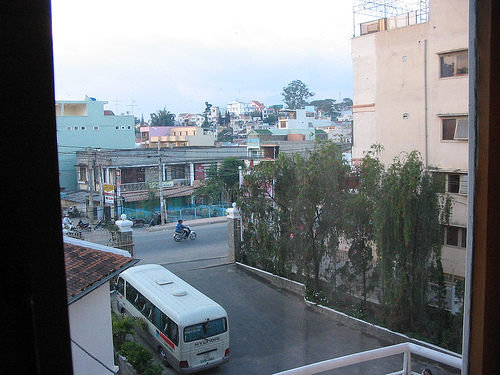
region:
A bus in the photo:
[111, 259, 230, 374]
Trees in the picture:
[295, 187, 398, 294]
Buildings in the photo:
[127, 137, 214, 223]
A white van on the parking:
[134, 264, 221, 372]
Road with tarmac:
[240, 275, 290, 346]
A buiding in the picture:
[410, 46, 443, 128]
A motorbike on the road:
[166, 222, 202, 248]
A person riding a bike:
[168, 218, 196, 239]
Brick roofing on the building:
[80, 246, 103, 276]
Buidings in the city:
[117, 105, 246, 181]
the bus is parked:
[112, 263, 236, 363]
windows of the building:
[418, 33, 482, 316]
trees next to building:
[250, 160, 435, 302]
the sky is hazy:
[153, 30, 270, 86]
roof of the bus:
[149, 265, 204, 317]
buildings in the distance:
[187, 115, 327, 150]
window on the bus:
[161, 306, 225, 348]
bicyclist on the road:
[163, 219, 199, 244]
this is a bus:
[95, 265, 239, 370]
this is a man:
[161, 210, 201, 246]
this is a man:
[165, 211, 190, 231]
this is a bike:
[160, 227, 212, 249]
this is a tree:
[370, 155, 455, 335]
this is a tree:
[280, 150, 351, 295]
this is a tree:
[232, 160, 313, 272]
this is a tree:
[112, 330, 159, 371]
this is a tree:
[178, 158, 248, 214]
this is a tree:
[329, 145, 396, 319]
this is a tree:
[379, 161, 445, 340]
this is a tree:
[279, 130, 355, 320]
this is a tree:
[247, 150, 306, 286]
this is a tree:
[221, 152, 289, 284]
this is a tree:
[193, 156, 249, 216]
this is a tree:
[110, 308, 146, 370]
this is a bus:
[112, 246, 231, 372]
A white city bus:
[110, 255, 236, 371]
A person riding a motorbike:
[165, 210, 200, 245]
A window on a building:
[430, 37, 475, 82]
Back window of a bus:
[180, 307, 231, 347]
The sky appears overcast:
[50, 0, 435, 122]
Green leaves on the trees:
[185, 135, 455, 335]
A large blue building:
[51, 87, 142, 192]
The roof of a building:
[57, 232, 147, 307]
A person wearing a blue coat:
[166, 212, 186, 234]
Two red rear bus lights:
[175, 337, 235, 372]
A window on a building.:
[436, 114, 468, 141]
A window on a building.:
[428, 222, 463, 254]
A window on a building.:
[416, 168, 468, 188]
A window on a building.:
[425, 267, 460, 302]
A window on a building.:
[120, 166, 154, 183]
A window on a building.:
[78, 166, 88, 183]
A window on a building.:
[105, 165, 115, 182]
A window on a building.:
[280, 120, 285, 132]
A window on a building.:
[306, 112, 314, 117]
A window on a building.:
[306, 121, 310, 125]